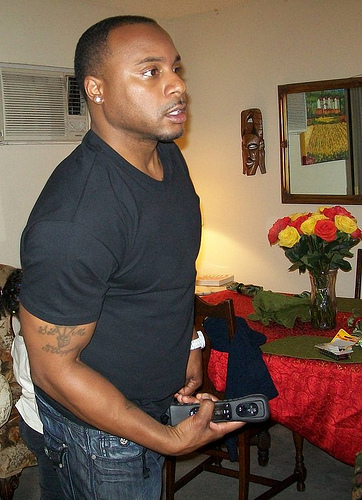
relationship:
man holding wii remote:
[12, 8, 243, 497] [162, 382, 276, 437]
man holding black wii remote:
[12, 8, 243, 497] [162, 382, 276, 437]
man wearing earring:
[12, 8, 243, 497] [81, 68, 107, 109]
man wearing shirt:
[12, 8, 243, 497] [13, 127, 215, 430]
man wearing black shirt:
[12, 8, 243, 497] [13, 127, 215, 430]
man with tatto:
[12, 8, 243, 497] [31, 319, 90, 363]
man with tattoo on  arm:
[12, 8, 243, 497] [31, 319, 90, 363]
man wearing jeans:
[12, 8, 243, 497] [27, 397, 173, 499]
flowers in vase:
[258, 195, 360, 334] [304, 257, 344, 331]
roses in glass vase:
[261, 200, 360, 266] [304, 257, 344, 331]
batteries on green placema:
[317, 323, 358, 359] [256, 322, 359, 374]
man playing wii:
[12, 8, 243, 497] [162, 382, 276, 437]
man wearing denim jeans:
[12, 8, 243, 497] [27, 397, 173, 499]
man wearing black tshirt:
[12, 8, 243, 497] [13, 127, 215, 430]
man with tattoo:
[12, 8, 243, 497] [31, 319, 90, 363]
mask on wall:
[236, 104, 273, 183] [189, 10, 273, 257]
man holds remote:
[12, 8, 243, 497] [162, 382, 276, 437]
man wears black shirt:
[12, 8, 243, 497] [13, 127, 215, 430]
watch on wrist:
[191, 323, 214, 353] [185, 324, 210, 357]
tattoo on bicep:
[31, 319, 90, 363] [9, 272, 108, 360]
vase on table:
[304, 257, 344, 331] [203, 282, 360, 451]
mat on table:
[256, 322, 359, 374] [203, 282, 360, 451]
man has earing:
[12, 8, 243, 497] [81, 68, 107, 109]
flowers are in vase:
[261, 200, 360, 266] [304, 257, 344, 331]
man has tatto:
[12, 8, 243, 497] [31, 319, 90, 363]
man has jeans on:
[12, 8, 243, 497] [27, 397, 173, 499]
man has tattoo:
[12, 8, 243, 497] [31, 319, 90, 363]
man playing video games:
[12, 8, 243, 497] [162, 382, 276, 437]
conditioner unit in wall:
[1, 57, 96, 152] [2, 6, 79, 193]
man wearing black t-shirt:
[12, 8, 243, 497] [13, 127, 215, 430]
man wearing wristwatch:
[12, 8, 243, 497] [191, 323, 214, 353]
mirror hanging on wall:
[275, 74, 360, 208] [177, 5, 356, 280]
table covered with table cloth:
[203, 282, 360, 451] [203, 285, 332, 429]